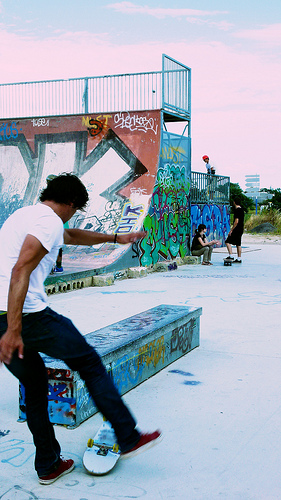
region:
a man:
[11, 205, 100, 457]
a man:
[45, 306, 113, 476]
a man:
[40, 289, 81, 448]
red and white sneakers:
[134, 427, 164, 451]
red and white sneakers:
[128, 416, 172, 454]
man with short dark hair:
[7, 154, 122, 231]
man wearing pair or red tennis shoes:
[3, 408, 198, 490]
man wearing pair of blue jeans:
[0, 286, 171, 491]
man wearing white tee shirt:
[0, 160, 124, 325]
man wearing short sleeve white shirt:
[0, 170, 126, 359]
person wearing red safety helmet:
[178, 143, 233, 201]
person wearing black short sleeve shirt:
[222, 189, 255, 270]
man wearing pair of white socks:
[222, 187, 254, 275]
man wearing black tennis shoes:
[222, 186, 257, 280]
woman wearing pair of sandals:
[188, 218, 217, 277]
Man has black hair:
[47, 180, 71, 195]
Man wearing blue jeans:
[43, 328, 84, 359]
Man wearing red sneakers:
[139, 430, 165, 452]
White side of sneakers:
[142, 442, 156, 446]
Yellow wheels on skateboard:
[85, 437, 121, 453]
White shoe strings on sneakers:
[60, 452, 68, 462]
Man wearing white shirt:
[18, 216, 43, 228]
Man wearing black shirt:
[235, 211, 241, 215]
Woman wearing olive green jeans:
[198, 249, 208, 254]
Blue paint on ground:
[161, 363, 205, 388]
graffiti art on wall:
[141, 198, 190, 258]